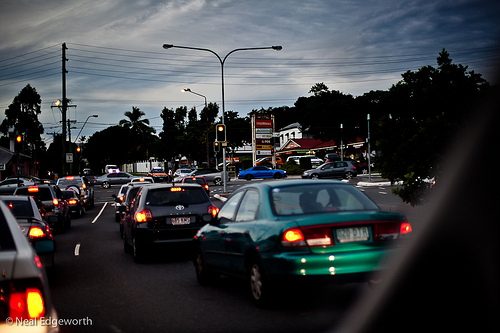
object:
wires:
[1, 42, 498, 88]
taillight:
[69, 199, 77, 206]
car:
[58, 188, 86, 218]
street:
[37, 163, 451, 331]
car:
[190, 178, 412, 302]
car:
[1, 202, 58, 332]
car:
[301, 161, 359, 180]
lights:
[398, 221, 412, 235]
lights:
[281, 226, 306, 246]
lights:
[133, 210, 146, 226]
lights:
[210, 205, 220, 221]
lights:
[27, 227, 48, 242]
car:
[0, 196, 55, 280]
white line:
[91, 201, 109, 224]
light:
[328, 250, 337, 260]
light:
[327, 265, 333, 273]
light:
[298, 255, 305, 265]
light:
[300, 268, 306, 274]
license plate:
[336, 227, 370, 243]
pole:
[59, 41, 68, 152]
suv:
[105, 165, 121, 174]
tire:
[244, 261, 281, 307]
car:
[238, 166, 288, 182]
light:
[75, 146, 81, 152]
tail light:
[81, 183, 89, 190]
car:
[56, 176, 95, 209]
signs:
[252, 118, 276, 155]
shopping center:
[212, 117, 375, 179]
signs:
[65, 153, 74, 163]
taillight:
[135, 209, 153, 223]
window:
[144, 187, 211, 207]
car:
[120, 183, 220, 263]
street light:
[215, 124, 225, 145]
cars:
[172, 168, 229, 186]